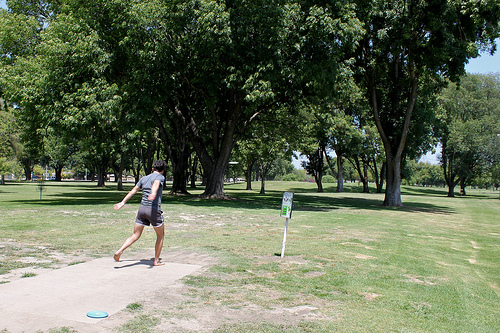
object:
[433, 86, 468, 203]
tree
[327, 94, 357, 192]
tree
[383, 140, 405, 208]
trunk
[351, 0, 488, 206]
tree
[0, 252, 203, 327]
mat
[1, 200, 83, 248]
grass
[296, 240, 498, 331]
grass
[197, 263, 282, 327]
grass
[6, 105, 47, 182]
trees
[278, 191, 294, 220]
sign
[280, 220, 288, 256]
post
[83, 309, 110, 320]
disc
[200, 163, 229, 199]
wood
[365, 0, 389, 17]
leaves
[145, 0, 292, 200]
tree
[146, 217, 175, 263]
leg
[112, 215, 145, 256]
leg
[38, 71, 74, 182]
tree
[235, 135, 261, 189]
trees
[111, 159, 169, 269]
man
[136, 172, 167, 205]
t shirt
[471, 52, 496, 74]
sky